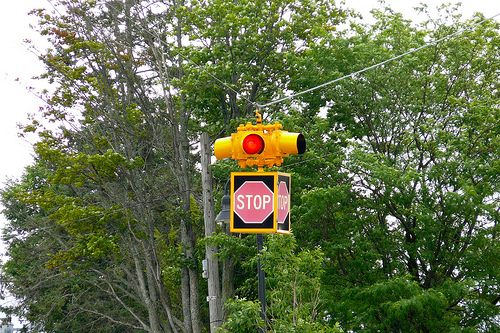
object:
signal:
[214, 123, 306, 167]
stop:
[237, 193, 271, 209]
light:
[243, 133, 264, 155]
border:
[272, 172, 278, 231]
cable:
[259, 15, 499, 110]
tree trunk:
[199, 135, 221, 331]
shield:
[282, 132, 306, 154]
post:
[255, 235, 270, 331]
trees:
[2, 136, 132, 330]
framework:
[212, 110, 304, 165]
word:
[236, 194, 271, 209]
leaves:
[427, 287, 437, 297]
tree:
[352, 10, 500, 329]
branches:
[98, 278, 148, 332]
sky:
[0, 2, 92, 184]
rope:
[97, 0, 499, 109]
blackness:
[264, 175, 273, 183]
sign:
[234, 180, 273, 223]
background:
[232, 180, 275, 225]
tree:
[184, 0, 314, 331]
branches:
[140, 239, 179, 332]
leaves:
[357, 148, 372, 157]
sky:
[335, 0, 500, 37]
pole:
[201, 151, 222, 332]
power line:
[258, 15, 499, 108]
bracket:
[250, 110, 272, 333]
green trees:
[103, 0, 175, 332]